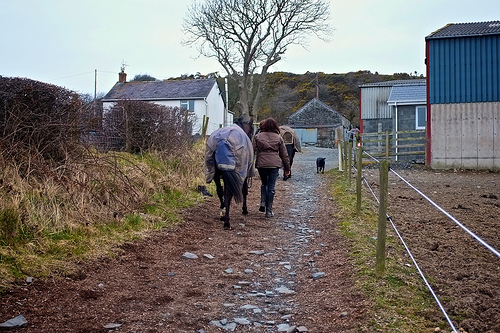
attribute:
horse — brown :
[189, 113, 260, 215]